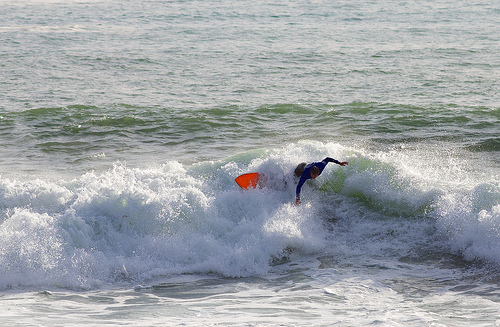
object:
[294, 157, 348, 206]
person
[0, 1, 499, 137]
ocean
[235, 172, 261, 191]
surfboard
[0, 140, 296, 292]
wave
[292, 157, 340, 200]
wetsuit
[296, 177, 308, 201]
arm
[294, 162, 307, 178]
shorts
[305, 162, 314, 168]
logo